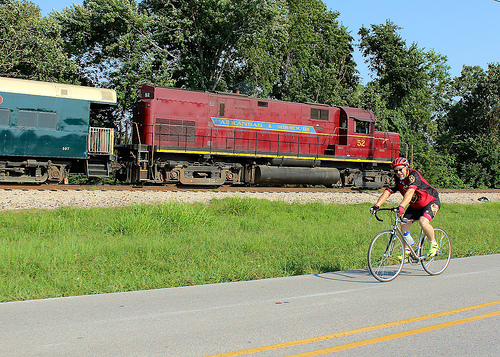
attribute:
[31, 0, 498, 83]
sky — blue 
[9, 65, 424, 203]
train — two tone, blue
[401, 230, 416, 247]
bottle — plastic, water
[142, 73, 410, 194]
train — red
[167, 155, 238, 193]
engine — red, train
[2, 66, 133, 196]
car — red, engine, train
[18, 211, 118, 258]
grass — brown , green , short 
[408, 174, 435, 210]
shirt — black, red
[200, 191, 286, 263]
grass — brown , green , short 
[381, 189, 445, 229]
shorts — red, black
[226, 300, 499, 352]
lines — yellow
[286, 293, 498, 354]
line — yellow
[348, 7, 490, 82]
sky — blue 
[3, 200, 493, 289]
grass — short , green , brown 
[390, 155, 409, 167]
helmet — red, bright, bikers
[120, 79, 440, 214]
train — red 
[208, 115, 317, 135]
banner — blue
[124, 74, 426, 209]
train — dusty, red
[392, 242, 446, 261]
shoes — green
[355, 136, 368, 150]
number — 52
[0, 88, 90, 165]
compartment — train